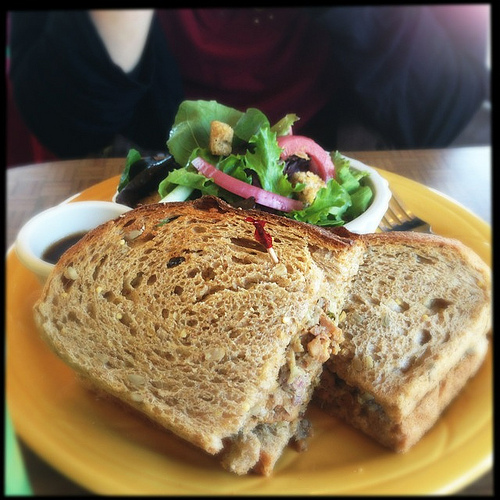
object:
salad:
[114, 99, 372, 230]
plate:
[0, 164, 500, 500]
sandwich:
[30, 201, 499, 482]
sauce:
[41, 229, 88, 265]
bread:
[314, 227, 499, 455]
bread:
[32, 202, 366, 477]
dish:
[15, 200, 134, 279]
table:
[0, 156, 496, 495]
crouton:
[209, 120, 233, 156]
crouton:
[293, 170, 328, 208]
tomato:
[276, 135, 336, 180]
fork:
[376, 190, 434, 233]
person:
[0, 0, 488, 162]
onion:
[189, 156, 305, 213]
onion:
[158, 185, 194, 203]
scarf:
[173, 12, 334, 137]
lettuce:
[247, 107, 288, 193]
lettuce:
[293, 149, 373, 226]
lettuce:
[167, 99, 238, 163]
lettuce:
[120, 149, 144, 190]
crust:
[73, 202, 346, 252]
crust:
[360, 236, 451, 279]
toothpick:
[244, 217, 279, 264]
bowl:
[328, 148, 392, 238]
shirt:
[161, 12, 337, 129]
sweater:
[6, 5, 494, 157]